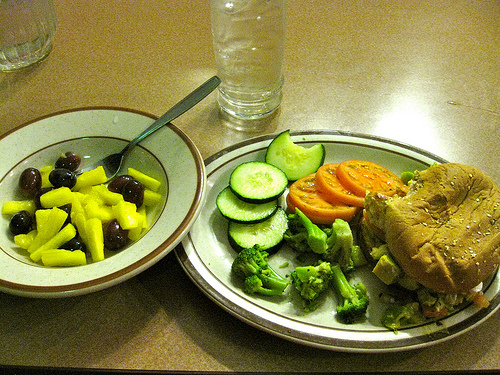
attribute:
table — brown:
[298, 0, 499, 141]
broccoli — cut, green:
[229, 246, 290, 301]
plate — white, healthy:
[171, 122, 498, 358]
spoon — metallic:
[74, 70, 222, 196]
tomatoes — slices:
[277, 159, 419, 223]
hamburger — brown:
[358, 162, 500, 336]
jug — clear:
[0, 2, 77, 72]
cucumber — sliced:
[231, 151, 286, 202]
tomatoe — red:
[335, 155, 407, 201]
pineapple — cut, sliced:
[78, 167, 105, 190]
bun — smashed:
[384, 162, 499, 289]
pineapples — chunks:
[69, 156, 109, 187]